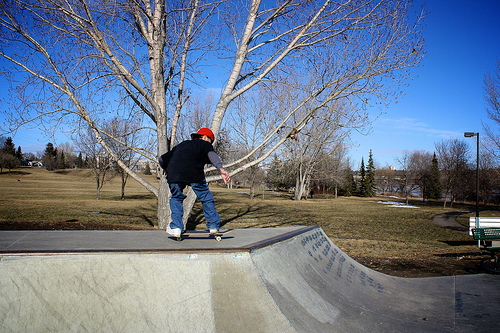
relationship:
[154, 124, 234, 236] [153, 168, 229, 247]
boy wearing jeans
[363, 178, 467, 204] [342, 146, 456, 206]
river hidden by trees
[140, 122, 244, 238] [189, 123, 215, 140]
boy wearing cap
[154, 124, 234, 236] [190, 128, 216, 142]
boy wearing cap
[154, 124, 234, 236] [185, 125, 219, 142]
boy wearing cap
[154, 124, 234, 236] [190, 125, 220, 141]
boy wearing cap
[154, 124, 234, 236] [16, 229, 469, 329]
boy on skateboarding ramp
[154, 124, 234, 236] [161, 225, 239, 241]
boy on skateboard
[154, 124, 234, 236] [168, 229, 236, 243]
boy on skateboard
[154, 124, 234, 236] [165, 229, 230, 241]
boy on skateboard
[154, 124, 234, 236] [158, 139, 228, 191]
boy wearing shirt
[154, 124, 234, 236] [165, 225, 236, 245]
boy on skateboard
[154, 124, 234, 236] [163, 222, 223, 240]
boy wearing tennis shoes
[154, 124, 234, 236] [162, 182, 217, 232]
boy wearing jeans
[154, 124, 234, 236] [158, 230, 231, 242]
boy on skateboard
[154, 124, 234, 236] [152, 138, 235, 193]
boy wearing shirt